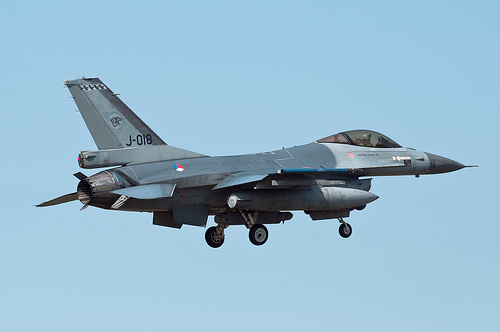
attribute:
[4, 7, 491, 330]
sky — clear, light blue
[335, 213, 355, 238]
wheel — down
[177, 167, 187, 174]
circle — red, white, blue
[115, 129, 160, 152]
writing — black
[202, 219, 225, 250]
wheel — black